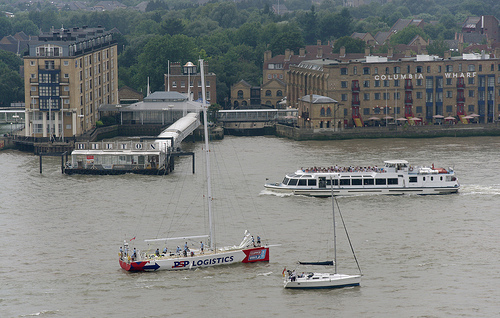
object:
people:
[300, 165, 308, 172]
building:
[291, 36, 500, 137]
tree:
[334, 36, 367, 55]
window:
[387, 177, 398, 185]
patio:
[71, 153, 161, 172]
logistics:
[190, 256, 237, 266]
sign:
[75, 142, 158, 151]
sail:
[331, 183, 363, 280]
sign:
[373, 71, 483, 81]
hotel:
[22, 25, 122, 138]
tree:
[319, 10, 351, 34]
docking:
[66, 117, 202, 176]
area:
[0, 4, 500, 318]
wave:
[455, 209, 488, 227]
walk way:
[218, 112, 275, 120]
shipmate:
[290, 269, 297, 281]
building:
[165, 57, 219, 103]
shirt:
[176, 248, 179, 252]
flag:
[128, 236, 137, 242]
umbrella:
[410, 117, 422, 120]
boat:
[118, 231, 271, 273]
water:
[15, 174, 111, 313]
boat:
[264, 160, 460, 197]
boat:
[284, 272, 362, 289]